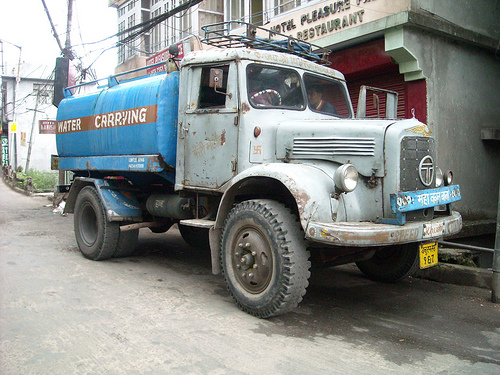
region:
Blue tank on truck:
[60, 71, 176, 178]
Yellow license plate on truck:
[420, 248, 445, 271]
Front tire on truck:
[221, 196, 314, 313]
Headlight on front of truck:
[336, 160, 360, 196]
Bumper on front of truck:
[317, 218, 464, 240]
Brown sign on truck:
[52, 106, 156, 131]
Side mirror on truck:
[207, 68, 236, 96]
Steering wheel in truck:
[254, 87, 287, 104]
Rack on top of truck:
[200, 18, 333, 69]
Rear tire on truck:
[69, 182, 134, 258]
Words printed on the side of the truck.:
[56, 109, 161, 131]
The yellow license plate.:
[415, 240, 442, 268]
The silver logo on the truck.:
[416, 151, 436, 187]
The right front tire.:
[218, 191, 308, 291]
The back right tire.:
[68, 186, 123, 259]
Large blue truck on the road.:
[27, 20, 473, 317]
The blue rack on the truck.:
[193, 13, 338, 67]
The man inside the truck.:
[307, 84, 332, 119]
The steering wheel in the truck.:
[249, 85, 283, 110]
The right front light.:
[335, 158, 371, 191]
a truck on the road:
[64, 47, 346, 367]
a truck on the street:
[40, 39, 382, 357]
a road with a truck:
[73, 49, 329, 316]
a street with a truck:
[103, 51, 385, 373]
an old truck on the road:
[30, 52, 382, 320]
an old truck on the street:
[29, 54, 483, 366]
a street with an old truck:
[55, 52, 400, 336]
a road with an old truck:
[87, 53, 419, 352]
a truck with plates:
[392, 171, 453, 285]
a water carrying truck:
[24, 54, 336, 281]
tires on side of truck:
[69, 170, 308, 324]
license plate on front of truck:
[412, 232, 443, 271]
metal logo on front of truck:
[412, 147, 437, 186]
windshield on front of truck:
[245, 59, 359, 121]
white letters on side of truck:
[54, 107, 154, 135]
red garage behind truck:
[333, 52, 423, 119]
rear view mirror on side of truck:
[201, 61, 234, 102]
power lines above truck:
[53, 2, 194, 89]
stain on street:
[251, 290, 498, 367]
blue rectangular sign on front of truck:
[385, 182, 466, 218]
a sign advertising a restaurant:
[247, 0, 409, 45]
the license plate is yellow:
[411, 236, 443, 271]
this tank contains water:
[43, 60, 184, 190]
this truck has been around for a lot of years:
[48, 18, 468, 319]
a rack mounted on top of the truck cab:
[189, 14, 338, 66]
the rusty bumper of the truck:
[305, 205, 469, 251]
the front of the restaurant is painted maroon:
[296, 36, 428, 128]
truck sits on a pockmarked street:
[2, 194, 376, 369]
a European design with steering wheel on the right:
[176, 43, 353, 133]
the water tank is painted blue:
[48, 54, 180, 183]